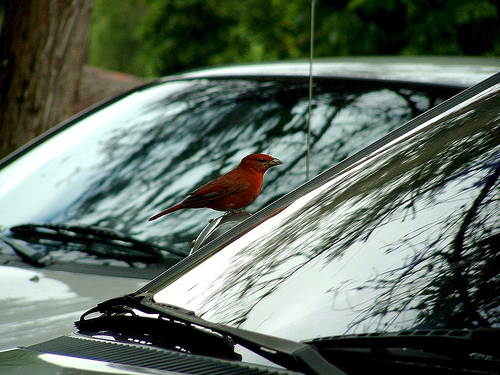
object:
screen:
[143, 72, 498, 347]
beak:
[270, 157, 283, 167]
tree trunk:
[1, 0, 95, 163]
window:
[0, 67, 471, 251]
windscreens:
[12, 75, 500, 375]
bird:
[146, 152, 282, 221]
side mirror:
[190, 209, 245, 247]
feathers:
[147, 190, 201, 222]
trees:
[0, 4, 499, 158]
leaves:
[86, 0, 499, 77]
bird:
[149, 152, 285, 225]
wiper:
[62, 288, 334, 371]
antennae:
[303, 0, 315, 179]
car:
[0, 49, 499, 374]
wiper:
[6, 221, 191, 263]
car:
[0, 70, 499, 373]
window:
[76, 71, 500, 374]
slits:
[70, 299, 328, 365]